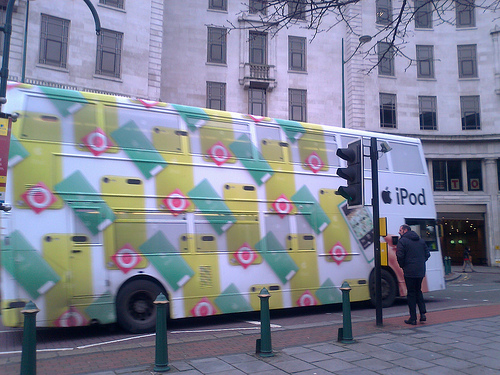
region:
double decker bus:
[8, 84, 444, 329]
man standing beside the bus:
[391, 219, 438, 327]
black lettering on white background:
[395, 184, 430, 212]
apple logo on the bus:
[377, 184, 393, 204]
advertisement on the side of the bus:
[9, 96, 371, 313]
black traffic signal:
[336, 142, 359, 202]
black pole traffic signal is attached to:
[363, 138, 388, 332]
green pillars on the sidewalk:
[17, 282, 354, 374]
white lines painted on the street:
[11, 301, 358, 357]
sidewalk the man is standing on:
[29, 294, 493, 372]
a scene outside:
[9, 1, 491, 373]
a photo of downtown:
[10, 6, 494, 367]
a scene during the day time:
[9, 5, 497, 367]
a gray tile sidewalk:
[97, 315, 498, 373]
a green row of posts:
[3, 261, 411, 372]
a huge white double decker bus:
[6, 63, 467, 367]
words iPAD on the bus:
[345, 155, 457, 243]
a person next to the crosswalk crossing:
[356, 118, 458, 349]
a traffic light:
[313, 118, 438, 348]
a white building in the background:
[7, 6, 498, 247]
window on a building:
[450, 95, 495, 131]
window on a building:
[450, 35, 480, 80]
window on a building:
[411, 90, 447, 140]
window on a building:
[368, 80, 404, 126]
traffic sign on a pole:
[332, 132, 374, 204]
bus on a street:
[35, 91, 332, 296]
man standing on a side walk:
[390, 216, 433, 316]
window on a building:
[87, 23, 128, 86]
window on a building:
[31, 6, 76, 66]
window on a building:
[203, 22, 237, 66]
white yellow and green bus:
[17, 140, 425, 344]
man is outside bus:
[382, 221, 436, 325]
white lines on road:
[198, 301, 291, 372]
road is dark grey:
[465, 273, 495, 310]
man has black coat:
[393, 228, 427, 272]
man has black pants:
[391, 271, 423, 330]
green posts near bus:
[314, 279, 391, 329]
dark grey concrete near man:
[440, 308, 498, 368]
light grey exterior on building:
[82, 2, 497, 149]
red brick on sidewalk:
[187, 307, 255, 365]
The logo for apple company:
[377, 188, 397, 212]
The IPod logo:
[395, 185, 432, 215]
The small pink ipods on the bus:
[11, 106, 366, 306]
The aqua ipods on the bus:
[27, 85, 407, 318]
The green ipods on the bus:
[20, 80, 376, 326]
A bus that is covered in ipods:
[18, 86, 463, 308]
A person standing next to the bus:
[390, 221, 428, 333]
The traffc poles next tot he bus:
[12, 293, 376, 364]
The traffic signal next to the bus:
[327, 125, 384, 339]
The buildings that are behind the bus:
[30, 15, 498, 239]